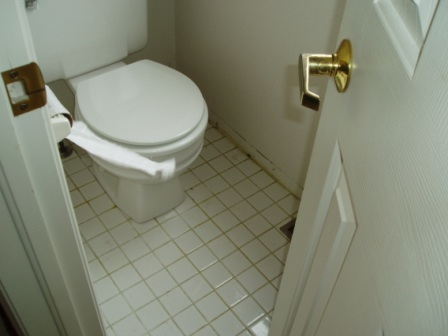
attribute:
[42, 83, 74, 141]
roll — empty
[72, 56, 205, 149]
toilet cover — closed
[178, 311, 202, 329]
tile — white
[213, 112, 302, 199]
baseboard — white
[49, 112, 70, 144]
holder — toilet paper roll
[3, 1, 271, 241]
commode — white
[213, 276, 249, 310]
tile — white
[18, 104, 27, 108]
screw — brass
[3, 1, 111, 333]
frame — door, white, wooden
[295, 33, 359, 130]
door knob — gold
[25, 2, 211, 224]
white toilet — porcelain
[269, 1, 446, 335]
door — bathroom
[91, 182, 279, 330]
floor — dirty, tiled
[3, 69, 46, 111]
stopper — door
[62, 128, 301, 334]
tile floor — white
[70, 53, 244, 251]
seat — white, wooden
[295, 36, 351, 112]
door handle — gold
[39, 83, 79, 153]
toilet paper — almost empty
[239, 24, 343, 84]
handle — door, gold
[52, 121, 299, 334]
floor — shiny, white, tiled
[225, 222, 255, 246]
tile — white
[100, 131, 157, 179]
paper — toilet, floating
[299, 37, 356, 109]
handle — gold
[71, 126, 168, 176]
paper — toilet